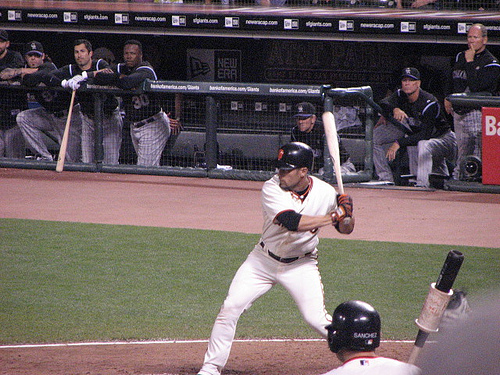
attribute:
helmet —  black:
[272, 142, 314, 173]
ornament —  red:
[277, 149, 283, 159]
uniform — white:
[242, 180, 356, 347]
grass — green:
[4, 232, 211, 340]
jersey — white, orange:
[257, 172, 340, 262]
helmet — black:
[275, 146, 316, 169]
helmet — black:
[270, 144, 310, 170]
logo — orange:
[272, 147, 284, 161]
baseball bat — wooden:
[315, 107, 365, 222]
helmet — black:
[270, 142, 317, 178]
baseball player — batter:
[199, 99, 341, 341]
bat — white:
[313, 102, 365, 239]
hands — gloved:
[63, 75, 87, 90]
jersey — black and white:
[111, 56, 164, 130]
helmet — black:
[260, 133, 382, 198]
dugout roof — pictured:
[6, 1, 498, 48]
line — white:
[1, 339, 433, 351]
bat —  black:
[404, 245, 466, 367]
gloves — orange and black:
[330, 192, 358, 229]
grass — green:
[10, 217, 499, 342]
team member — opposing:
[0, 39, 84, 164]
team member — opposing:
[43, 37, 126, 164]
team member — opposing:
[91, 37, 170, 164]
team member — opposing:
[367, 64, 458, 186]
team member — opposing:
[448, 21, 499, 189]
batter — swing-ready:
[191, 136, 353, 373]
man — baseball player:
[200, 154, 371, 361]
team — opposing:
[18, 43, 203, 161]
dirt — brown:
[1, 168, 499, 373]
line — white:
[3, 327, 209, 348]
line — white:
[18, 334, 158, 354]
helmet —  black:
[321, 298, 384, 356]